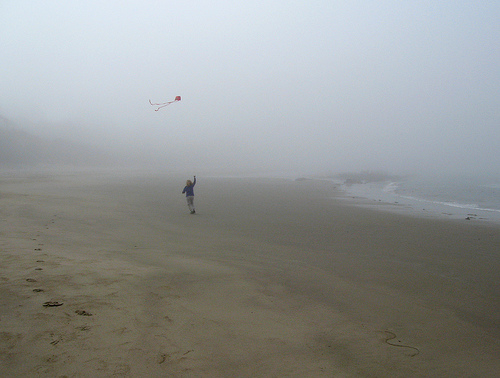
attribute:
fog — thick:
[4, 4, 492, 206]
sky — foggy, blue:
[9, 3, 496, 50]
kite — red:
[147, 90, 184, 114]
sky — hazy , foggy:
[24, 7, 489, 202]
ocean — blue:
[319, 165, 499, 218]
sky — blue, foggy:
[1, 2, 498, 177]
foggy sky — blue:
[3, 0, 498, 205]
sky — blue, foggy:
[6, 4, 496, 193]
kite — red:
[147, 73, 209, 133]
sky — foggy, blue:
[155, 17, 396, 109]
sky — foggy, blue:
[84, 19, 449, 143]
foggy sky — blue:
[243, 4, 495, 104]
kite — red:
[151, 91, 186, 115]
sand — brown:
[104, 270, 165, 346]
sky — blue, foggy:
[258, 16, 400, 96]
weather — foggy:
[62, 62, 432, 321]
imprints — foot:
[32, 245, 104, 338]